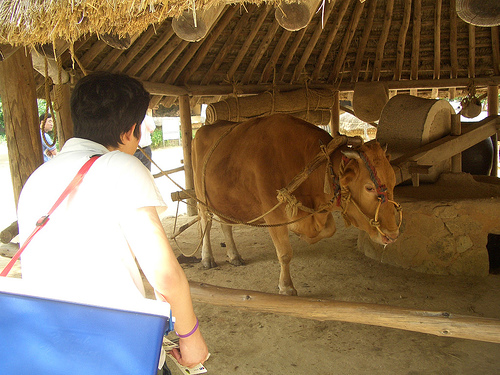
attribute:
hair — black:
[68, 68, 150, 149]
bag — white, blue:
[1, 234, 200, 371]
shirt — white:
[21, 76, 218, 356]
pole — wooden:
[272, 264, 492, 369]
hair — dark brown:
[66, 63, 157, 152]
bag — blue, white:
[460, 93, 491, 129]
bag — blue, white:
[2, 283, 184, 373]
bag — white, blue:
[1, 145, 171, 374]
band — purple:
[177, 319, 202, 347]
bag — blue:
[2, 274, 187, 372]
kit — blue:
[2, 293, 178, 373]